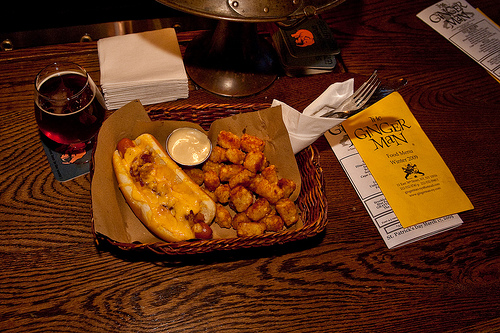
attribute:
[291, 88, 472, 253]
menus — yellow, white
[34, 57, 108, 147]
glass — full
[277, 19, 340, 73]
coaster — green, red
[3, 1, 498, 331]
table — wooden, brown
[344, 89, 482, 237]
menu — yellow